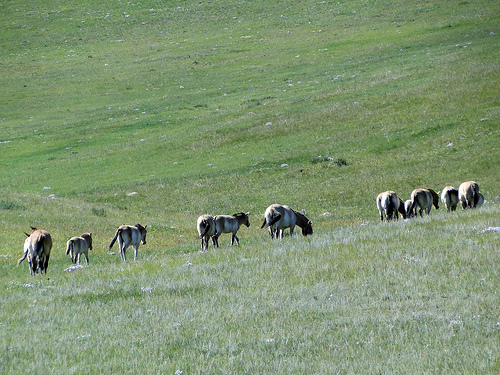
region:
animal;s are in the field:
[61, 162, 495, 236]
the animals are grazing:
[86, 192, 453, 282]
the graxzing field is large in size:
[88, 67, 445, 332]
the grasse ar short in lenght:
[211, 250, 358, 368]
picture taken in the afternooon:
[12, 139, 370, 349]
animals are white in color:
[21, 192, 495, 357]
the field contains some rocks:
[157, 100, 312, 137]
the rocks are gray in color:
[173, 68, 283, 138]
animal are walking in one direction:
[363, 160, 491, 250]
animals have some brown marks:
[337, 184, 487, 241]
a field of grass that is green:
[263, 243, 429, 337]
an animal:
[102, 214, 159, 265]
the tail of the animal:
[104, 233, 121, 252]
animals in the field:
[15, 223, 153, 266]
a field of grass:
[88, 48, 240, 132]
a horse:
[263, 199, 323, 237]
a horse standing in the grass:
[103, 216, 158, 263]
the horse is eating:
[374, 186, 405, 219]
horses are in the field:
[368, 181, 483, 218]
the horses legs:
[229, 231, 239, 245]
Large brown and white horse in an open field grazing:
[15, 214, 56, 280]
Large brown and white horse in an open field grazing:
[62, 227, 86, 264]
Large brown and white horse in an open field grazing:
[112, 212, 166, 274]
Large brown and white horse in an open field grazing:
[187, 203, 209, 248]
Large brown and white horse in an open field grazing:
[215, 204, 250, 245]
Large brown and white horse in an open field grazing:
[264, 186, 316, 238]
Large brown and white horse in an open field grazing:
[370, 185, 402, 211]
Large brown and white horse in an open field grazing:
[411, 179, 437, 216]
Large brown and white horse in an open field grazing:
[435, 179, 460, 209]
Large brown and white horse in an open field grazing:
[456, 167, 479, 208]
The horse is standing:
[24, 223, 52, 272]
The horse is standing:
[58, 225, 95, 270]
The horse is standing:
[211, 205, 252, 244]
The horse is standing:
[102, 222, 148, 262]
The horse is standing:
[193, 205, 210, 247]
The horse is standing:
[256, 185, 316, 245]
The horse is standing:
[373, 185, 398, 220]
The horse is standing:
[408, 184, 439, 216]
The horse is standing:
[439, 180, 459, 212]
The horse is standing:
[452, 175, 483, 212]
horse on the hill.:
[105, 215, 152, 262]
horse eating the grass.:
[292, 205, 318, 244]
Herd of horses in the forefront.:
[3, 175, 493, 281]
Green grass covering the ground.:
[3, 1, 494, 373]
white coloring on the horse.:
[108, 217, 149, 260]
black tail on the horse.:
[380, 192, 402, 221]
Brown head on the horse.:
[232, 205, 253, 233]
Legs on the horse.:
[25, 256, 49, 273]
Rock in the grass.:
[122, 186, 139, 201]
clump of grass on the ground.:
[330, 152, 350, 169]